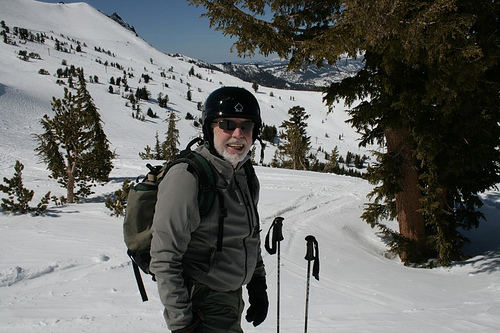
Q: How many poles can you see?
A: Two.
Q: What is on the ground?
A: Snow.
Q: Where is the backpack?
A: On the man's back.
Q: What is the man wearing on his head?
A: A helmet.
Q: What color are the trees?
A: Green.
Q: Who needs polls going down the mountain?
A: Skiers.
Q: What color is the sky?
A: Blue.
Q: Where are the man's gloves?
A: On this hands.